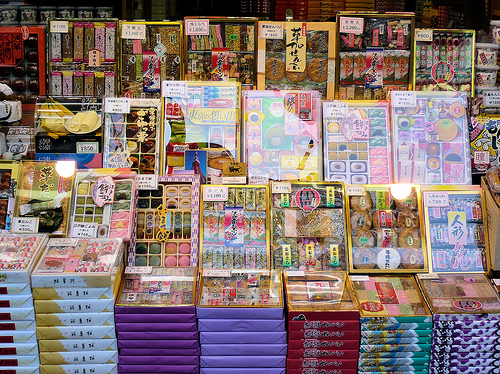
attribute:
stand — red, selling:
[0, 1, 498, 370]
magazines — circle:
[104, 97, 158, 190]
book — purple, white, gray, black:
[116, 269, 202, 373]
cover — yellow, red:
[284, 272, 358, 314]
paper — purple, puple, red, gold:
[116, 303, 196, 314]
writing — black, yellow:
[289, 28, 304, 70]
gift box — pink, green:
[183, 17, 257, 88]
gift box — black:
[258, 21, 337, 100]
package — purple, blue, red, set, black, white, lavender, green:
[119, 23, 184, 100]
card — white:
[164, 84, 238, 178]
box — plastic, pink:
[413, 29, 475, 98]